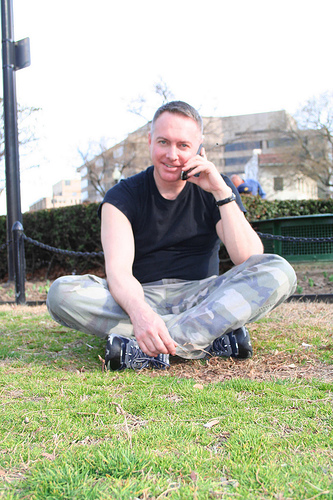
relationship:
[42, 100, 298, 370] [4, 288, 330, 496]
man on ground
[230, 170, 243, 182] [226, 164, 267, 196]
head on man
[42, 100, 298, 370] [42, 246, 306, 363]
man wears army pants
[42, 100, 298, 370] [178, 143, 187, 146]
man has eye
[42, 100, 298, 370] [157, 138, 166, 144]
man has eye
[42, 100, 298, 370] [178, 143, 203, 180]
man has phone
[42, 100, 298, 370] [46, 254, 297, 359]
man has army pants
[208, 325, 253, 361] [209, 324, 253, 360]
foot has sneaker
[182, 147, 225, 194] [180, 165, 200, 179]
hand has phone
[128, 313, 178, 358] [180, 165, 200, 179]
hand has phone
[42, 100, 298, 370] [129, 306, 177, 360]
man has hand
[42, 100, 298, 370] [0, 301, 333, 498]
man on grass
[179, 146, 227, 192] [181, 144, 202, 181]
hand holds cell phone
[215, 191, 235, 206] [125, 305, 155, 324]
watch on wrist